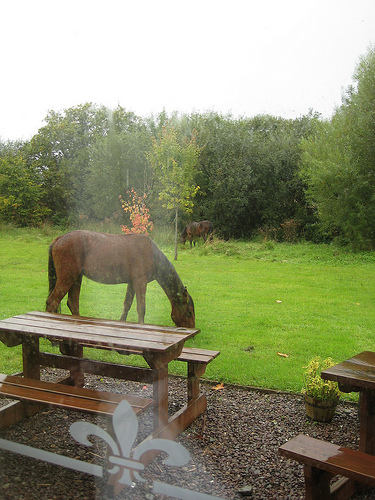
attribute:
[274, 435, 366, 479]
bench — wooden, wet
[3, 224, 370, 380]
field — grassy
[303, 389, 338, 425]
planter — small, wooden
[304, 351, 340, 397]
flowers — yellow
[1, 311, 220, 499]
table — for picnic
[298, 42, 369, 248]
tree — green, thick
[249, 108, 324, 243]
tree — green, thick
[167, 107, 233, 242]
tree — green, thick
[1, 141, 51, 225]
tree — green, thick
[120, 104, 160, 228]
tree — green, thick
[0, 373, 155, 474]
bench — wooden, brown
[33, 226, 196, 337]
horse — brown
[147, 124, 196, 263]
tree — small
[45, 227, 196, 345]
horse — wet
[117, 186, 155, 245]
tree — red